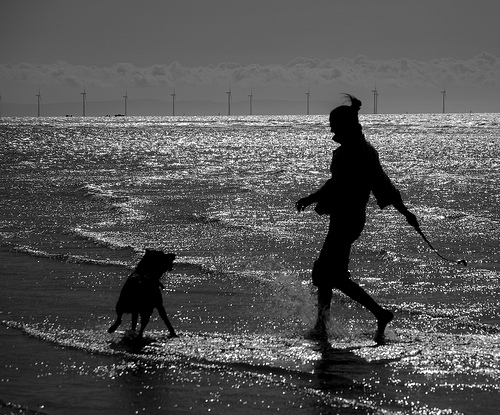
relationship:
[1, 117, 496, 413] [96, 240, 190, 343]
water below dog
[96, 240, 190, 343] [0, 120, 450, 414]
dog on beach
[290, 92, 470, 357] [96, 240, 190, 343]
woman with dog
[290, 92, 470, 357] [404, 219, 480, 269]
woman has leash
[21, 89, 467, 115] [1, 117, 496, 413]
windmills beyond water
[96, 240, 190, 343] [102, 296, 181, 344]
dog has legs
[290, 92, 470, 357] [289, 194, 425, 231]
woman has hands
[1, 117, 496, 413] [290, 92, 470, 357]
water under woman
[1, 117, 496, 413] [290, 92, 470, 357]
water underneath woman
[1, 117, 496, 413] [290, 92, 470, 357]
water below woman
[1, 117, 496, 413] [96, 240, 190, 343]
water underneath dog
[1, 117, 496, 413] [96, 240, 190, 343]
water under dog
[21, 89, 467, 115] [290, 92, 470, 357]
windmills behind woman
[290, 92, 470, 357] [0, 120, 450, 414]
woman on beach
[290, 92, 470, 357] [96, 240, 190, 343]
woman playing with dog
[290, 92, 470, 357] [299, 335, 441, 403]
woman casting shadow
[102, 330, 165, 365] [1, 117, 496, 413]
dog's shadow in water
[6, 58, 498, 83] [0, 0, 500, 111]
clouds in sky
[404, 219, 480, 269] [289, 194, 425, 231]
leash in hands